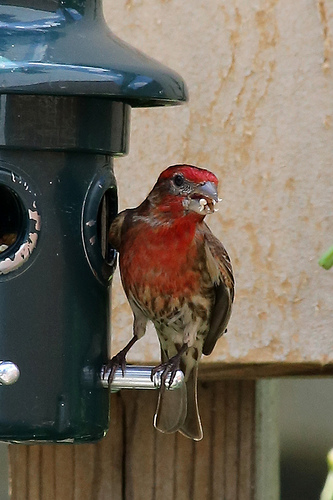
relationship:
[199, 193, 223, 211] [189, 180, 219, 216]
feed in beak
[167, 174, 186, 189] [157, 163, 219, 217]
eye on bird head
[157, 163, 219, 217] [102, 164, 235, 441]
bird head of bird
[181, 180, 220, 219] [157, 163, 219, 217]
beak on bird head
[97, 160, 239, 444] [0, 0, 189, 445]
bird sitting at bird feeder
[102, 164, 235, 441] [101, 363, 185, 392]
bird sitting on perch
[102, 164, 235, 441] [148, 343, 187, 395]
bird has claws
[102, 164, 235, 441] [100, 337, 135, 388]
bird has claws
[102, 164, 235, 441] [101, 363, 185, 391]
bird perching on perch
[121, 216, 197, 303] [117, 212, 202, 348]
patch on body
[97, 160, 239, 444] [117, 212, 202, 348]
bird has body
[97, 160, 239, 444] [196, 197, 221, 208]
bird eating twigs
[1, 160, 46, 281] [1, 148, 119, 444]
shape built into tube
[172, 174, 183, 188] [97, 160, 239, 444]
eye belonging to bird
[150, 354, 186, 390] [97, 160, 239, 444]
claw belonging to bird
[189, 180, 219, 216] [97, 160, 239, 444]
beak belonging to bird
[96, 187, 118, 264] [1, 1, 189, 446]
hole leading to bird feeder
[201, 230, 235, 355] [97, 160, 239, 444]
left wing belonging to bird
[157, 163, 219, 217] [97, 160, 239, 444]
bird head belonging to bird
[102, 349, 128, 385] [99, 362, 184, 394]
claw standing on perch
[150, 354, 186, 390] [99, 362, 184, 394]
claw standing on perch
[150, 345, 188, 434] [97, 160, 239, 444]
tail feather adorning bird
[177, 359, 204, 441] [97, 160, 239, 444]
tail feather adorning bird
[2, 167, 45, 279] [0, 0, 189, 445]
paint wearing off bird feeder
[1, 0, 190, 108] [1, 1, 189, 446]
cover sealing bird feeder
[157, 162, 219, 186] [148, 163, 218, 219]
top adorning bird head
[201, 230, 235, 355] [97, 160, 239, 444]
left wing attached to bird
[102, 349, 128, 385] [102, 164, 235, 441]
claw of bird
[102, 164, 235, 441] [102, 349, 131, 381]
bird has claw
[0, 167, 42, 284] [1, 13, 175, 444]
paint on bird feeder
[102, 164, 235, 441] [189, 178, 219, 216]
bird has beak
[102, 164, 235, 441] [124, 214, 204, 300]
bird has chest